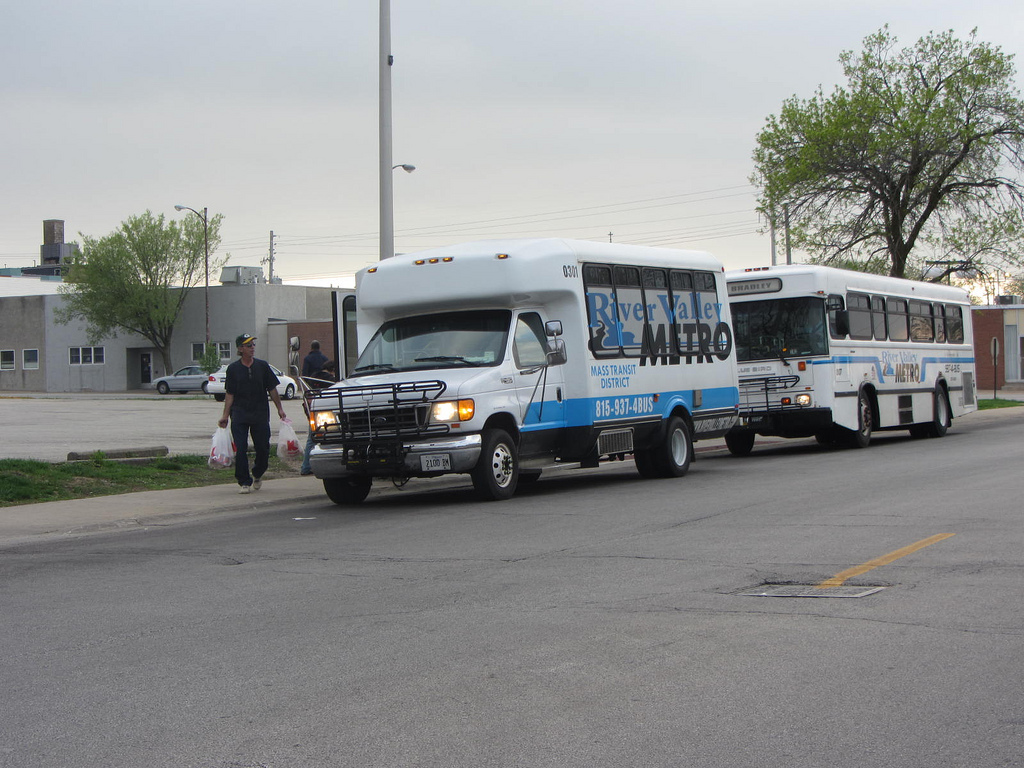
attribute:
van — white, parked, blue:
[308, 239, 743, 509]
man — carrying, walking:
[216, 332, 290, 494]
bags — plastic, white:
[205, 419, 308, 476]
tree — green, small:
[51, 210, 232, 377]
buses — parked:
[305, 238, 979, 509]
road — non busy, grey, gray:
[2, 417, 1022, 762]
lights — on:
[308, 402, 478, 437]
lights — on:
[779, 392, 811, 408]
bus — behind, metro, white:
[724, 265, 978, 455]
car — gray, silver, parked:
[151, 364, 219, 397]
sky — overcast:
[2, 0, 1022, 312]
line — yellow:
[820, 529, 958, 591]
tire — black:
[473, 429, 522, 502]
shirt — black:
[225, 357, 279, 425]